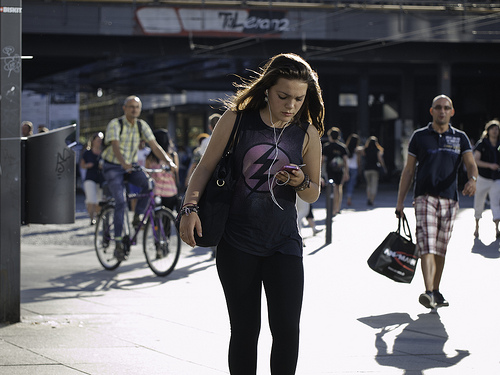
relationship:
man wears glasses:
[368, 89, 480, 312] [432, 103, 455, 114]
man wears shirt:
[368, 89, 480, 312] [405, 118, 475, 204]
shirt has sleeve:
[405, 118, 475, 204] [458, 134, 473, 163]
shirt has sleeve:
[405, 118, 475, 204] [403, 131, 425, 160]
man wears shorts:
[368, 89, 480, 312] [407, 190, 463, 261]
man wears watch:
[368, 89, 480, 312] [464, 174, 481, 184]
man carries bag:
[368, 89, 480, 312] [367, 209, 420, 287]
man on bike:
[88, 87, 187, 279] [88, 151, 186, 278]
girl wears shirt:
[174, 49, 326, 372] [221, 109, 312, 261]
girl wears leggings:
[174, 49, 326, 372] [213, 236, 304, 374]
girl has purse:
[174, 49, 326, 372] [175, 92, 247, 255]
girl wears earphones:
[174, 49, 326, 372] [262, 90, 303, 214]